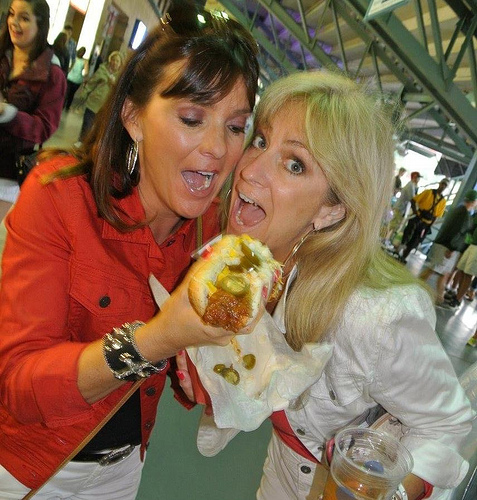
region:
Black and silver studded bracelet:
[104, 319, 169, 387]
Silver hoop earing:
[126, 131, 140, 184]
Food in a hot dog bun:
[190, 233, 284, 334]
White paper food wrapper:
[189, 348, 322, 422]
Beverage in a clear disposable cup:
[325, 423, 402, 498]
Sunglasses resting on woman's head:
[155, 9, 268, 53]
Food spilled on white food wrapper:
[214, 348, 258, 386]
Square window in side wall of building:
[130, 14, 148, 50]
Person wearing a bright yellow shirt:
[414, 171, 454, 228]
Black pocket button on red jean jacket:
[96, 292, 114, 312]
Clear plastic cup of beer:
[315, 422, 413, 497]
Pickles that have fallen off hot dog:
[207, 353, 264, 385]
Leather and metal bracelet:
[92, 316, 169, 388]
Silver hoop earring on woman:
[121, 135, 144, 177]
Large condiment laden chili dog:
[173, 231, 288, 337]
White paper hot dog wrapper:
[134, 275, 329, 433]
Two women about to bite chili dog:
[70, 22, 418, 354]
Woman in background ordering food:
[0, 1, 62, 184]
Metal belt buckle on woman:
[101, 444, 146, 468]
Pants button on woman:
[290, 457, 322, 482]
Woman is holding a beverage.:
[225, 65, 468, 495]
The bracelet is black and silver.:
[97, 316, 167, 393]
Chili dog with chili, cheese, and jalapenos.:
[187, 232, 278, 334]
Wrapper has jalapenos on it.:
[148, 283, 322, 429]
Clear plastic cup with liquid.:
[316, 426, 420, 498]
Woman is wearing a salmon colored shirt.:
[0, 11, 278, 498]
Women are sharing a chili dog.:
[2, 11, 474, 498]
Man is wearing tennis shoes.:
[380, 170, 420, 251]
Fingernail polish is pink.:
[175, 370, 185, 381]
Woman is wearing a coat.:
[67, 48, 125, 146]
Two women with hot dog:
[8, 6, 467, 428]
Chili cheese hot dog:
[187, 232, 280, 338]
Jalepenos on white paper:
[205, 352, 264, 395]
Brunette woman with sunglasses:
[22, 2, 249, 224]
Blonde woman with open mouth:
[228, 67, 420, 343]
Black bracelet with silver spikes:
[94, 316, 171, 393]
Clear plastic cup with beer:
[320, 420, 418, 499]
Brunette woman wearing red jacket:
[6, 13, 255, 489]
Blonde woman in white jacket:
[224, 57, 468, 496]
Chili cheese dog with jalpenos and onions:
[186, 223, 277, 339]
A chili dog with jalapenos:
[191, 226, 278, 365]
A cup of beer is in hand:
[315, 416, 449, 498]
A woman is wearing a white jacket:
[220, 251, 459, 458]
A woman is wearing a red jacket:
[25, 153, 254, 486]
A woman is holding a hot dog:
[71, 216, 321, 377]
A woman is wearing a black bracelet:
[89, 310, 193, 399]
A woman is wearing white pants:
[4, 427, 170, 498]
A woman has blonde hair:
[264, 73, 415, 333]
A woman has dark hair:
[25, 22, 284, 208]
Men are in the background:
[398, 164, 475, 277]